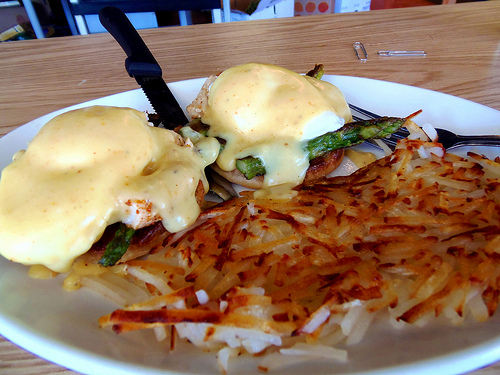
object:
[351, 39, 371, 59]
paperclip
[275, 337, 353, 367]
hash brown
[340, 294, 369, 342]
hash brown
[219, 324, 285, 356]
hash brown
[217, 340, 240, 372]
hash brown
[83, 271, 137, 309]
hash brown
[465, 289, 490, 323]
hash brown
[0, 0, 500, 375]
table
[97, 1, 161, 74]
handle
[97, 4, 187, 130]
knife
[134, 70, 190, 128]
blade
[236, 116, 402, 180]
asperagus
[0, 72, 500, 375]
plate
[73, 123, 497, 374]
hashbrowns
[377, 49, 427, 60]
paperclip